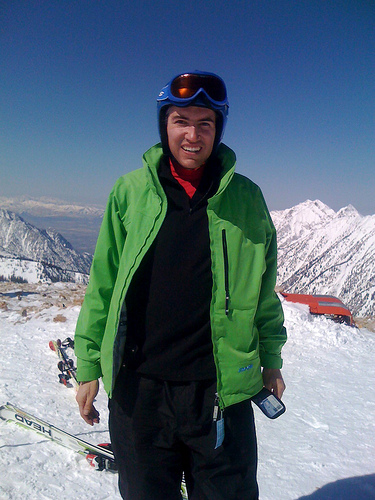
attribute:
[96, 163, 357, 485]
jacket — green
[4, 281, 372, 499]
snow — grey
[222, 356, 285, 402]
letters — blue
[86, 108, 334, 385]
jacket — green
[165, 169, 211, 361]
shirt — black, orange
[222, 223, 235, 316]
zipper — black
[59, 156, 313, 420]
jacket — green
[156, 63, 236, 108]
goggles — snow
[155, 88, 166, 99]
letter s — white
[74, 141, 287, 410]
jacket — green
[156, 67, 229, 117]
goggles — blue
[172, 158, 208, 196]
shirt — red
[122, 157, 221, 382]
shirt — black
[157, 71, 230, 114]
goggles — blue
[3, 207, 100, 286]
mountain — faraway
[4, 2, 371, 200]
sky — clear, blue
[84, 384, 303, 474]
pants — black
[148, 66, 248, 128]
glasses — blue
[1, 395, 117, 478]
ski — snow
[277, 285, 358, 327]
vehicle — orange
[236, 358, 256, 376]
design — blue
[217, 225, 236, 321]
zipper — black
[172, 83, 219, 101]
lenses — orange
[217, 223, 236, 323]
zippers — black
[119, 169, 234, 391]
shirt — black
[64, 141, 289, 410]
parka — green